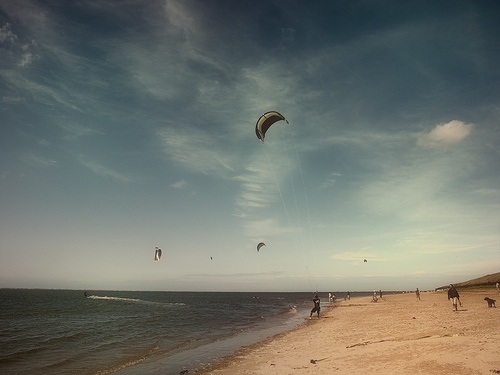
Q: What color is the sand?
A: Brown.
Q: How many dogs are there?
A: One.